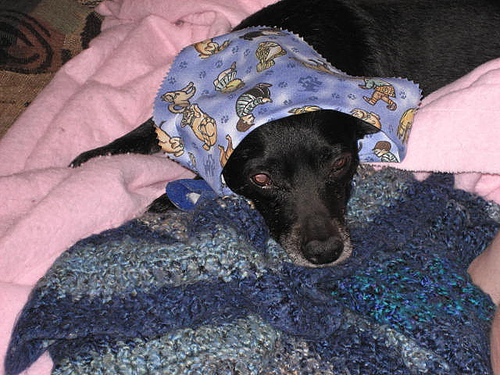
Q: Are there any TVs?
A: No, there are no tvs.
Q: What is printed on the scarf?
A: The character is printed on the scarf.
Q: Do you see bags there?
A: No, there are no bags.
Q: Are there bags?
A: No, there are no bags.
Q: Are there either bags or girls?
A: No, there are no bags or girls.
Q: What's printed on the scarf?
A: The character is printed on the scarf.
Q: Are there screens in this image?
A: No, there are no screens.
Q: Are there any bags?
A: No, there are no bags.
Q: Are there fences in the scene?
A: No, there are no fences.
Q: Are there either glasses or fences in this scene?
A: No, there are no fences or glasses.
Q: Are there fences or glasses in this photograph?
A: No, there are no fences or glasses.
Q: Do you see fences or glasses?
A: No, there are no fences or glasses.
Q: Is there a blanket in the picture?
A: Yes, there is a blanket.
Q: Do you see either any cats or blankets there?
A: Yes, there is a blanket.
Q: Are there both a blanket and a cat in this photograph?
A: No, there is a blanket but no cats.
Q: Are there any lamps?
A: No, there are no lamps.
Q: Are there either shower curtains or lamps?
A: No, there are no lamps or shower curtains.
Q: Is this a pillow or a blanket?
A: This is a blanket.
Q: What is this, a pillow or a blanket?
A: This is a blanket.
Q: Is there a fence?
A: No, there are no fences.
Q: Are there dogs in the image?
A: Yes, there is a dog.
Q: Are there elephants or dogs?
A: Yes, there is a dog.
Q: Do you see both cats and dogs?
A: No, there is a dog but no cats.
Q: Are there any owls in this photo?
A: No, there are no owls.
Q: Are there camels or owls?
A: No, there are no owls or camels.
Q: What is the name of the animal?
A: The animal is a dog.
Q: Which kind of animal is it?
A: The animal is a dog.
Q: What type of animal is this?
A: This is a dog.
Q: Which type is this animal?
A: This is a dog.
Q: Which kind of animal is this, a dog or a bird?
A: This is a dog.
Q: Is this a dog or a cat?
A: This is a dog.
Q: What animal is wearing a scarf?
A: The dog is wearing a scarf.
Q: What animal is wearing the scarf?
A: The dog is wearing a scarf.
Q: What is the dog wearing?
A: The dog is wearing a scarf.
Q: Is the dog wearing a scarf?
A: Yes, the dog is wearing a scarf.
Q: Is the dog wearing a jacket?
A: No, the dog is wearing a scarf.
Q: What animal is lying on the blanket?
A: The dog is lying on the blanket.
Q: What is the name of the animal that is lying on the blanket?
A: The animal is a dog.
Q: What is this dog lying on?
A: The dog is lying on the blanket.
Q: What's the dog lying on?
A: The dog is lying on the blanket.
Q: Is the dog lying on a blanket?
A: Yes, the dog is lying on a blanket.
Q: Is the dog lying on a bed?
A: No, the dog is lying on a blanket.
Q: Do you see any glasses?
A: No, there are no glasses.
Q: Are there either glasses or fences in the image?
A: No, there are no glasses or fences.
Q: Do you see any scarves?
A: Yes, there is a scarf.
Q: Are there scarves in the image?
A: Yes, there is a scarf.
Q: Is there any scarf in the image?
A: Yes, there is a scarf.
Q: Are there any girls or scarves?
A: Yes, there is a scarf.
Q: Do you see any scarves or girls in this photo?
A: Yes, there is a scarf.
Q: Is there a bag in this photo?
A: No, there are no bags.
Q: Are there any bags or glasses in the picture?
A: No, there are no bags or glasses.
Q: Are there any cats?
A: No, there are no cats.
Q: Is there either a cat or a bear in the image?
A: No, there are no cats or bears.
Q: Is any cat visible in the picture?
A: No, there are no cats.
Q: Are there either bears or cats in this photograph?
A: No, there are no cats or bears.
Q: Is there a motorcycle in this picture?
A: No, there are no motorcycles.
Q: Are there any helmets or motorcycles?
A: No, there are no motorcycles or helmets.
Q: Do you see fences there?
A: No, there are no fences.